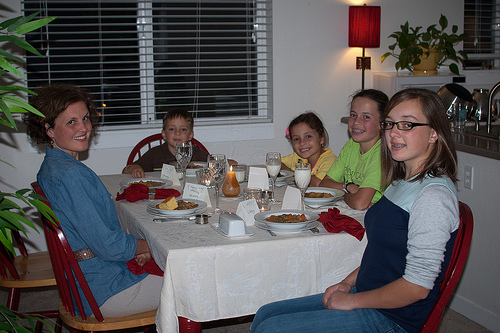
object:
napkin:
[315, 205, 365, 242]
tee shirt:
[326, 137, 392, 203]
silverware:
[152, 214, 209, 221]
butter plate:
[216, 212, 247, 237]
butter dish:
[212, 210, 252, 239]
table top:
[99, 165, 365, 250]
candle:
[222, 165, 240, 197]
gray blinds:
[20, 2, 272, 124]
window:
[16, 0, 276, 132]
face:
[289, 122, 320, 158]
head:
[378, 87, 447, 162]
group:
[25, 88, 463, 330]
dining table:
[97, 162, 376, 332]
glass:
[294, 160, 312, 209]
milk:
[292, 168, 310, 190]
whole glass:
[174, 141, 311, 213]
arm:
[350, 192, 455, 309]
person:
[253, 87, 461, 333]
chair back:
[30, 182, 104, 323]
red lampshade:
[349, 5, 381, 47]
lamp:
[347, 5, 382, 91]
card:
[235, 199, 261, 226]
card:
[245, 165, 269, 190]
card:
[159, 163, 180, 186]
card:
[182, 182, 209, 205]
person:
[318, 88, 389, 210]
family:
[18, 74, 495, 326]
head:
[26, 78, 101, 153]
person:
[22, 80, 163, 317]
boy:
[121, 107, 239, 178]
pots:
[437, 83, 474, 112]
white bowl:
[253, 209, 321, 229]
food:
[266, 213, 308, 224]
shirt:
[36, 145, 148, 316]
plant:
[387, 9, 469, 76]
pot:
[409, 49, 439, 77]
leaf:
[449, 63, 461, 76]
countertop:
[453, 127, 496, 151]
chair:
[127, 132, 212, 166]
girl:
[280, 111, 338, 187]